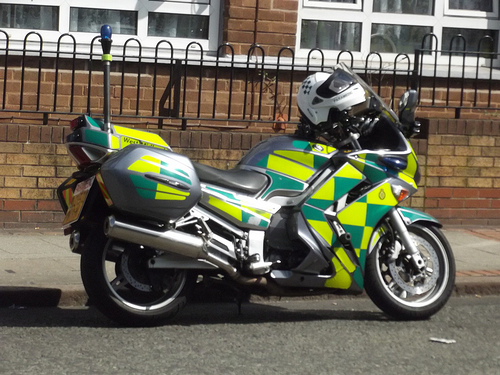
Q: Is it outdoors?
A: Yes, it is outdoors.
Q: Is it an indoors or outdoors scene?
A: It is outdoors.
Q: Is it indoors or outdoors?
A: It is outdoors.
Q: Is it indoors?
A: No, it is outdoors.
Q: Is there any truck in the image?
A: No, there are no trucks.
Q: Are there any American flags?
A: No, there are no American flags.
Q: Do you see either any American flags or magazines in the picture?
A: No, there are no American flags or magazines.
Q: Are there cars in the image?
A: No, there are no cars.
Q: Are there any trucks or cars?
A: No, there are no cars or trucks.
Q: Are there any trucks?
A: No, there are no trucks.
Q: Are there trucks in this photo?
A: No, there are no trucks.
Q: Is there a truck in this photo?
A: No, there are no trucks.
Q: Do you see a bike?
A: Yes, there is a bike.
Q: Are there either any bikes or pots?
A: Yes, there is a bike.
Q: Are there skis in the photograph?
A: No, there are no skis.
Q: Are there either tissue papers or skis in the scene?
A: No, there are no skis or tissue papers.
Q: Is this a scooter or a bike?
A: This is a bike.